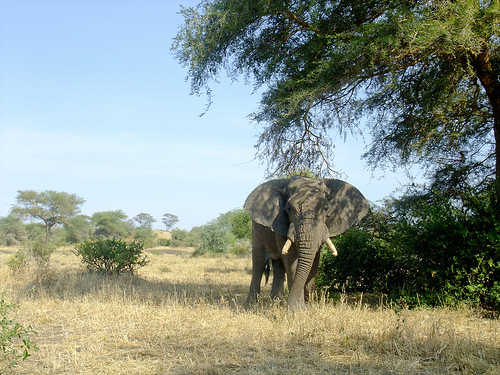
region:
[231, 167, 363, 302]
a large gray elephant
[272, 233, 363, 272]
white tusks on a large elephant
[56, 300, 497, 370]
dead grass on the ground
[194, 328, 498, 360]
the shadows of trees on the brown grass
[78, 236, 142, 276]
a small green bush in the grass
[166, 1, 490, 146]
a large green tree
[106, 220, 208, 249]
a small brown hillside with trees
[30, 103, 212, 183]
a blue sky with thin white clouds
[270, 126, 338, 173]
leafless branches hanging down from a tree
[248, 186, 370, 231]
the large grey ears of an elephant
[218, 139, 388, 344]
the elephant is gray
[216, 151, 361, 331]
the elephant's skin is wrinkled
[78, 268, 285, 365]
the grasses are dry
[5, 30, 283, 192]
the sky is clear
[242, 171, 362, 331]
the elephant has trunk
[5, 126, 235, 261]
the trees in the distance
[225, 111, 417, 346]
the elephant has tusks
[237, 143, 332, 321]
the elephant is standing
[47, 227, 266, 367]
grasses on the ground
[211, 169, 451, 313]
elephant has wide ears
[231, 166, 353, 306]
gray african elephant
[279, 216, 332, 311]
gray elephant trunk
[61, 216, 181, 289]
small green bush in the background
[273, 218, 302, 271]
right tusk of elephant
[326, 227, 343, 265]
left tusk of elephant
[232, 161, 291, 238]
left ear of elephant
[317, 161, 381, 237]
right ear of elephant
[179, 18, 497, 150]
tall tree with green bushes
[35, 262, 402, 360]
golden dead grass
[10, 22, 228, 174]
beautiful clear blue sky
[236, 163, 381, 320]
elephant in a field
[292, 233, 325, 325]
trunk of an elephant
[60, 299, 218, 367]
brown grasses of a field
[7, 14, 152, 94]
blue sky in the distance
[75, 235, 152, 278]
green bush in the grass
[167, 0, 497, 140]
green leaves on a tree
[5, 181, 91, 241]
tree in the distance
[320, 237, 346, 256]
left tusk of an elephant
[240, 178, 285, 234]
right ear of an elephant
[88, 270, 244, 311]
shadow on the ground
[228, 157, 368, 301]
Elephant standing in the middle of a field.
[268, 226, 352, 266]
Large ivory elephant tusks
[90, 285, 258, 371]
Dead and dry grass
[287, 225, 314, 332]
Long elephant trunk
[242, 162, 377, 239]
Large ears on elephant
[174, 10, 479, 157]
Tree overhanging the field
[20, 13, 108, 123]
Sky with no clouds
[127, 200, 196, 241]
Trees on a hill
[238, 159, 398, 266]
Elephant looking at photographer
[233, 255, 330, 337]
The elephant has four legs